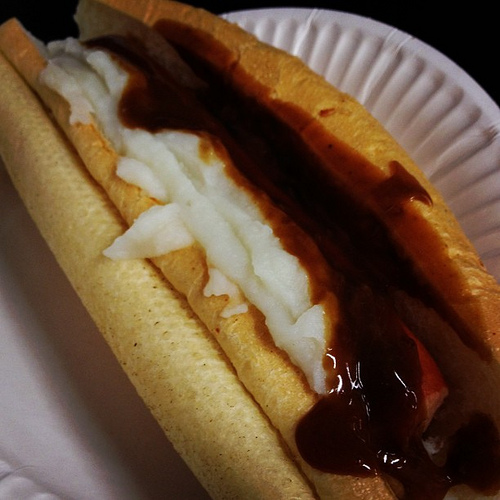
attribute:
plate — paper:
[229, 7, 498, 262]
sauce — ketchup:
[341, 357, 406, 412]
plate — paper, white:
[1, 7, 497, 498]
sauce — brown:
[154, 14, 490, 342]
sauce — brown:
[81, 15, 495, 498]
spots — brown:
[0, 61, 313, 499]